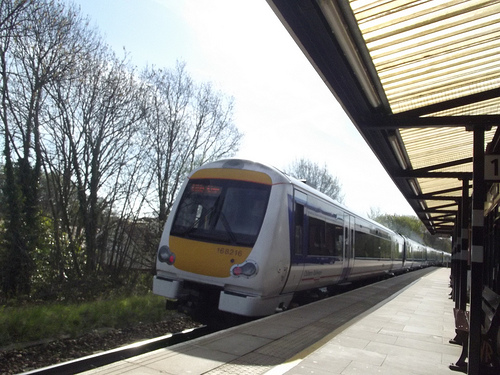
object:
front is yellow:
[157, 156, 276, 295]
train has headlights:
[232, 261, 259, 277]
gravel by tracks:
[2, 368, 12, 373]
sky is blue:
[72, 1, 211, 69]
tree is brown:
[150, 67, 189, 230]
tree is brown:
[70, 57, 110, 275]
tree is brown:
[12, 6, 59, 277]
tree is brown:
[293, 157, 341, 200]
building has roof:
[266, 0, 500, 349]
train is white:
[149, 158, 448, 315]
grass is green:
[0, 294, 174, 333]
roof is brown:
[346, 0, 500, 144]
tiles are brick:
[90, 264, 452, 375]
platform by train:
[75, 263, 452, 375]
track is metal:
[5, 326, 196, 375]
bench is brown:
[446, 283, 497, 374]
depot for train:
[82, 0, 500, 375]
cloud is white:
[192, 0, 273, 70]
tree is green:
[0, 162, 32, 300]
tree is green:
[47, 210, 71, 298]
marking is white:
[472, 208, 485, 227]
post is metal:
[466, 127, 485, 375]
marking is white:
[470, 246, 484, 262]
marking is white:
[461, 228, 470, 240]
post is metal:
[459, 176, 469, 310]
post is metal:
[455, 203, 461, 308]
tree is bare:
[17, 0, 64, 172]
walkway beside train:
[77, 266, 447, 375]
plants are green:
[0, 164, 43, 300]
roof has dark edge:
[267, 0, 446, 237]